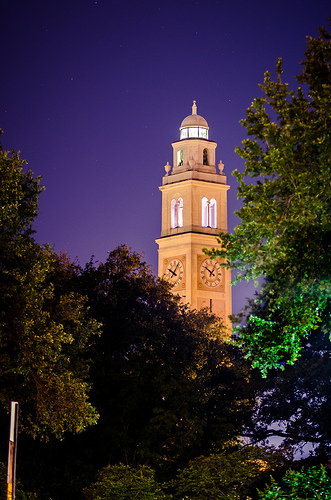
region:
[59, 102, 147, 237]
the sky is dark purple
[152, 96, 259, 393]
the tower is illuminated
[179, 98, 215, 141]
The dome of the clock is lit.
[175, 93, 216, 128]
The top of the dome is tan.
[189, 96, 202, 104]
There is a tan ball on top of the dome.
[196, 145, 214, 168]
The window is open.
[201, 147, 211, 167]
The window is dark.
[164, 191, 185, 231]
There is a light in the window.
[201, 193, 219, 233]
There is a light in the window.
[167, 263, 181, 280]
The hands on the clock are black.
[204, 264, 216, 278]
The hands on the clock are black.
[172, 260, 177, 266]
The number on the clock is black.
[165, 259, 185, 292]
a clock is on the tower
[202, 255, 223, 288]
a clock is on the tower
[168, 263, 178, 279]
the dials are made of metal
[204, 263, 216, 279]
the dials are made of metal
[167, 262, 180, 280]
the dials are black in color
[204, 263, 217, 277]
the dials are black in color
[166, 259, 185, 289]
the clock has roman numerals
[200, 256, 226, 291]
the clock has roman numerals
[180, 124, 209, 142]
the tower is lighted on top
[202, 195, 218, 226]
the tower has arched windows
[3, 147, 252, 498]
A dark green group of trees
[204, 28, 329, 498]
A bright green, tall tree.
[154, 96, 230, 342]
A tower in the background.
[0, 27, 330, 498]
A group of multicolored trees in the foreground.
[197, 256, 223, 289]
A round clock face on the tower.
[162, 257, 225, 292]
There are two clock faces visible.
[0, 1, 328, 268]
A dark, night time sky.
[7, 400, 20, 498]
A bar in the foreground.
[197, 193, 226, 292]
A group of two lighted windows above the clock.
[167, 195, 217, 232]
A group of four lighted windows.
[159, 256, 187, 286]
Clock on the building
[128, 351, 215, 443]
Trees in the photo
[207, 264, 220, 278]
Arms of a clock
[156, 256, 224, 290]
Two clocks mounted on the building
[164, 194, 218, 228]
Light on the building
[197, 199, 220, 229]
Window on the tower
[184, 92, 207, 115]
Cross at the top of the building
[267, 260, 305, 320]
Leaves on the tree